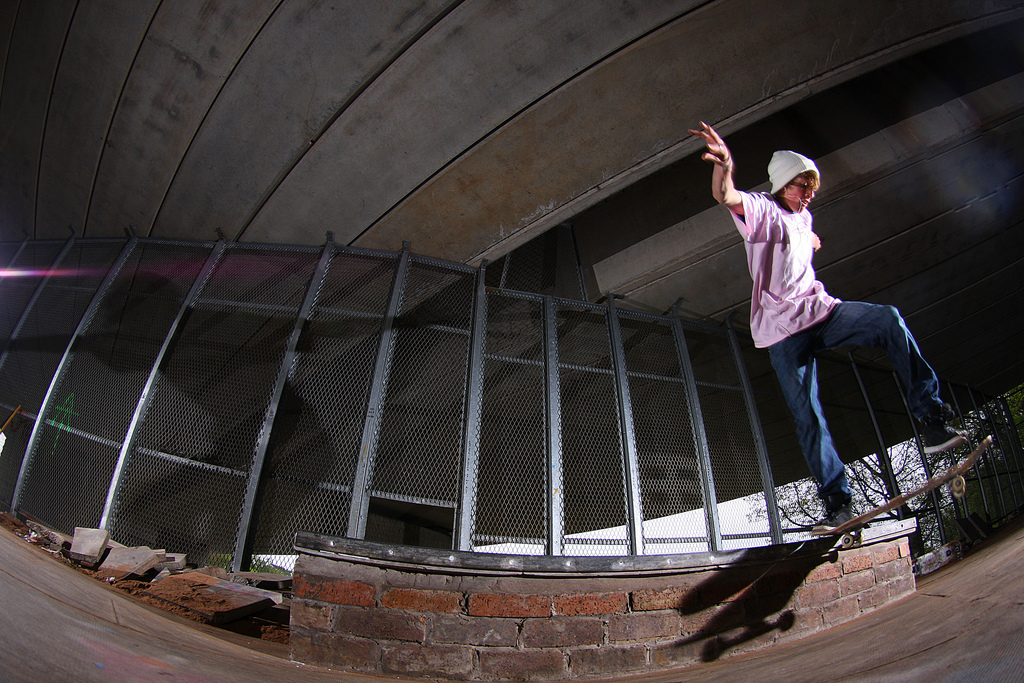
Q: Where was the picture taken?
A: At the skateboard park.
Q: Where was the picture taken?
A: At the skateboard ramp.